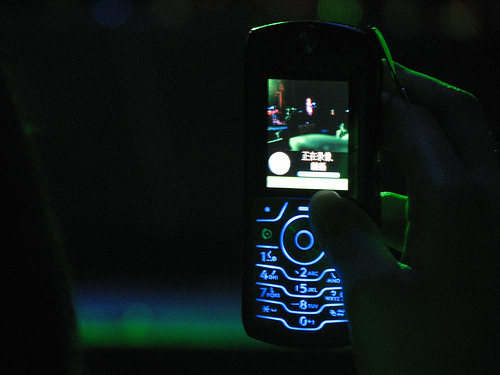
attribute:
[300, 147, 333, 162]
logo — small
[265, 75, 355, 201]
screen — illuminated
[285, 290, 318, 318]
eight — number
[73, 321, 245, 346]
stripe — green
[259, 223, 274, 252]
button — green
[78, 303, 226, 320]
stripe — blue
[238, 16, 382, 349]
phone — on, cell